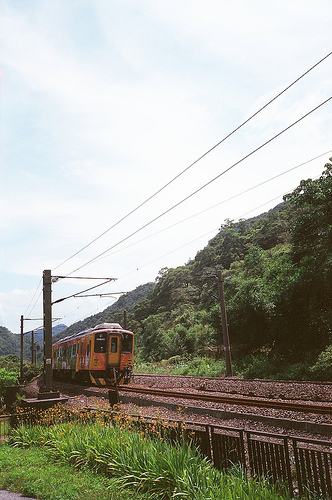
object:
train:
[48, 322, 135, 390]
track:
[106, 371, 331, 418]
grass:
[0, 402, 297, 497]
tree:
[281, 178, 330, 334]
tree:
[242, 244, 284, 328]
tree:
[154, 265, 186, 300]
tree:
[187, 321, 201, 358]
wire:
[49, 48, 332, 275]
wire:
[91, 141, 331, 266]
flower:
[149, 425, 156, 435]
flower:
[120, 417, 125, 422]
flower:
[188, 429, 196, 440]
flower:
[68, 406, 76, 419]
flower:
[94, 399, 102, 410]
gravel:
[64, 394, 171, 420]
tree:
[142, 314, 168, 356]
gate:
[71, 405, 331, 493]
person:
[110, 339, 118, 358]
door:
[107, 330, 122, 371]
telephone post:
[42, 267, 54, 389]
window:
[70, 342, 74, 357]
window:
[65, 343, 72, 357]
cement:
[1, 478, 35, 500]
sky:
[0, 3, 331, 334]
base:
[22, 387, 68, 411]